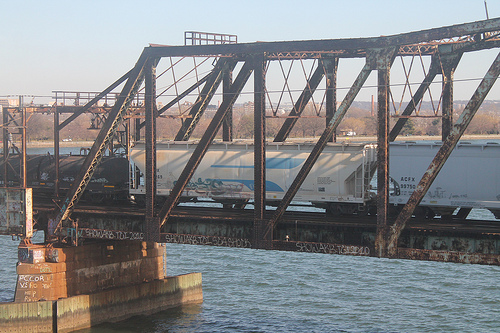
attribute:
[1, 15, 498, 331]
bridge — in the picture, brown, rusty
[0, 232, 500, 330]
water — in the picture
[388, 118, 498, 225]
train car — white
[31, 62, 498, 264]
bridge — lower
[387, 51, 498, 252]
beam — in the picture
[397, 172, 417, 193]
black writing — Black 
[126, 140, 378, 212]
train — White 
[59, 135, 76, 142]
building — in the picture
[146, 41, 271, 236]
beam brige — in the picture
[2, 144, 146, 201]
train car — brown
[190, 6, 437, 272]
bridge — in the picture